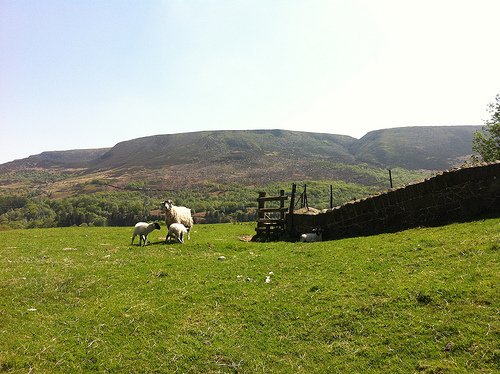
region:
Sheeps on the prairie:
[117, 188, 204, 251]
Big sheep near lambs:
[153, 192, 202, 235]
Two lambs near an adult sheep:
[121, 216, 198, 251]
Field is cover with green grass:
[12, 216, 497, 364]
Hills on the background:
[3, 121, 499, 186]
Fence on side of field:
[251, 158, 496, 247]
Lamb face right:
[125, 212, 163, 250]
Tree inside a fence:
[463, 86, 498, 159]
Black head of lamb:
[151, 215, 163, 232]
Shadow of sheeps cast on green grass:
[136, 233, 178, 255]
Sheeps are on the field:
[94, 171, 207, 281]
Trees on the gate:
[430, 82, 499, 161]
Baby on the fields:
[108, 210, 220, 255]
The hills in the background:
[13, 133, 470, 245]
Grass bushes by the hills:
[16, 170, 318, 235]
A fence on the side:
[246, 145, 479, 257]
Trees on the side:
[462, 75, 499, 188]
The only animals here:
[67, 175, 269, 253]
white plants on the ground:
[204, 234, 299, 306]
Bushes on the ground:
[5, 176, 371, 301]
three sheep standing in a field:
[106, 193, 211, 260]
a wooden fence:
[239, 181, 301, 240]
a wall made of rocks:
[252, 154, 494, 258]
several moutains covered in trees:
[0, 119, 451, 225]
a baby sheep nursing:
[156, 189, 198, 251]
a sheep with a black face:
[122, 215, 163, 247]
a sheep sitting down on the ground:
[291, 225, 331, 243]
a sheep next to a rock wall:
[278, 202, 343, 266]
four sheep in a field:
[106, 185, 353, 270]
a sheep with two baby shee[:
[106, 188, 198, 254]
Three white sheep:
[119, 195, 207, 255]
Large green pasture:
[0, 212, 499, 372]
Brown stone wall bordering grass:
[255, 148, 499, 245]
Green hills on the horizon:
[25, 115, 499, 155]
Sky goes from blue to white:
[0, 25, 499, 140]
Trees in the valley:
[3, 162, 499, 227]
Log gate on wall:
[248, 184, 290, 245]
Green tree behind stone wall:
[464, 75, 499, 170]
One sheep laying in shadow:
[291, 224, 338, 261]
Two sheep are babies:
[120, 210, 202, 255]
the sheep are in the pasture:
[121, 187, 219, 267]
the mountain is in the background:
[83, 125, 364, 176]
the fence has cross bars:
[253, 181, 304, 241]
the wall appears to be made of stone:
[280, 155, 495, 256]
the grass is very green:
[88, 272, 267, 340]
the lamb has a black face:
[118, 200, 161, 257]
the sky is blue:
[50, 32, 145, 69]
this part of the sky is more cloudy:
[263, 30, 405, 81]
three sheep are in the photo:
[123, 182, 215, 257]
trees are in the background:
[55, 179, 260, 219]